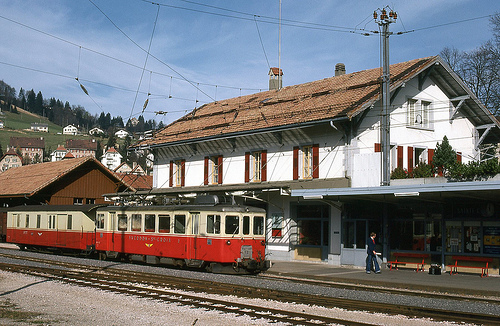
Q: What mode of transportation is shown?
A: Train.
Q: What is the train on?
A: Tracks.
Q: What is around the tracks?
A: Gravel.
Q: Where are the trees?
A: Top of the hill.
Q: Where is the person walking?
A: Sidewalk.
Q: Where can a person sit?
A: Benches.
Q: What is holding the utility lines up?
A: Poles.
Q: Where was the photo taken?
A: At a train station.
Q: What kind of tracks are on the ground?
A: Train tracks.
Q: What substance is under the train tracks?
A: Gravel.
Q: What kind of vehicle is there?
A: A train.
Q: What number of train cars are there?
A: Two.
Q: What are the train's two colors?
A: Red and beige.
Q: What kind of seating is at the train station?
A: Benches.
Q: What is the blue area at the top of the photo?
A: The sky.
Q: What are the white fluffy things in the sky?
A: Clouds.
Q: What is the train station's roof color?
A: Brown.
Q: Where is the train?
A: Train tracks.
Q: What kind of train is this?
A: Red and tan train.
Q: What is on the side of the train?
A: Windows.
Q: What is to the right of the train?
A: Two story white house.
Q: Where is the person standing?
A: Train platform.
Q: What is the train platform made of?
A: Cement.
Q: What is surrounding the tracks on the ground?
A: Gravel and rocks.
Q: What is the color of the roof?
A: Brown.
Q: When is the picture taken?
A: Daytime.